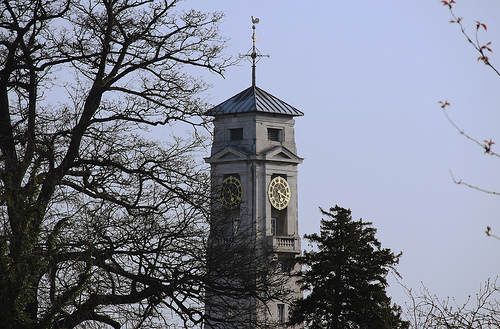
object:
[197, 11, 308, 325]
clock tower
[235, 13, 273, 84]
rod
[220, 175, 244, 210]
clocks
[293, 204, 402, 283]
tree top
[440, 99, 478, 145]
branch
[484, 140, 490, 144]
leaves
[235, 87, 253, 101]
spot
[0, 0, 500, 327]
sky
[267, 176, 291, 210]
clock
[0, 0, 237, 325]
tree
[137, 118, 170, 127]
branches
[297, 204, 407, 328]
tree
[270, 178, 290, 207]
face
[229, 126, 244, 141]
window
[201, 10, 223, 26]
branches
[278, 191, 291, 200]
hands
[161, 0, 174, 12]
branches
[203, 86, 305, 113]
roof